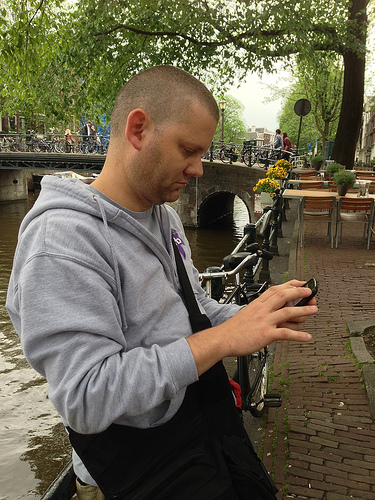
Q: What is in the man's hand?
A: Phone.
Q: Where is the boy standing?
A: By riverfront.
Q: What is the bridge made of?
A: Bricks.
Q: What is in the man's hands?
A: Phone.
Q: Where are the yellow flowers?
A: Along railing.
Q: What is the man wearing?
A: Sweatshirt.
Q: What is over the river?
A: Bridge.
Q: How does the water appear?
A: Calm.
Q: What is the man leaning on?
A: Railing.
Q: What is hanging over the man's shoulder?
A: Black bag.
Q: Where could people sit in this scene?
A: Table and chairs.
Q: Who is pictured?
A: A man.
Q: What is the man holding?
A: A phone.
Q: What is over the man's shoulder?
A: A black bag.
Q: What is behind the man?
A: A river.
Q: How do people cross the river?
A: The bridge.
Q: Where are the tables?
A: In front of the tree.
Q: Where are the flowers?
A: Hanging from the rail.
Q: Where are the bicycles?
A: Chained to the rail.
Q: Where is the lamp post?
A: On the bridge.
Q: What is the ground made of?
A: Bricks.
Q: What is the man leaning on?
A: Railing.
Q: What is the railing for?
A: Safety.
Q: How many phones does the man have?
A: 1.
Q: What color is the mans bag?
A: Black.